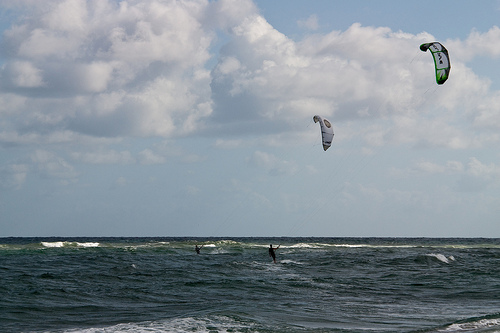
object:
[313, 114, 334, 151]
sails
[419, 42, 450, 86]
sail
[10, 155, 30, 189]
cloud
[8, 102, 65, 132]
cloud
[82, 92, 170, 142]
cloud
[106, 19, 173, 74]
cloud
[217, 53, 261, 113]
cloud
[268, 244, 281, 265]
person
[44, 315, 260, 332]
foam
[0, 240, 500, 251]
foam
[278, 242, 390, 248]
ocean wave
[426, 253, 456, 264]
froth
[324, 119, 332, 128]
circle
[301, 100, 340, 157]
sail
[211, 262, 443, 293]
wave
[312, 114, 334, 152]
white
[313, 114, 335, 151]
kite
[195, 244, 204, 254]
person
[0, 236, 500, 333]
ocean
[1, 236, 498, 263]
wave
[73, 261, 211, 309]
ripples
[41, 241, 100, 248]
caps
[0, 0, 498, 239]
sky